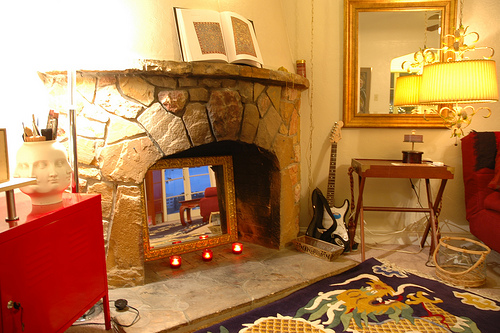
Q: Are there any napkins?
A: No, there are no napkins.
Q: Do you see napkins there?
A: No, there are no napkins.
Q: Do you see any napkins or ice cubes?
A: No, there are no napkins or ice cubes.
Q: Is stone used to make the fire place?
A: Yes, the fire place is made of stone.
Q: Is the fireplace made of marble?
A: No, the fireplace is made of stone.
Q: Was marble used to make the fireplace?
A: No, the fireplace is made of stone.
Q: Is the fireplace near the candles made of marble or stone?
A: The fire place is made of stone.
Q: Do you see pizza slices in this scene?
A: No, there are no pizza slices.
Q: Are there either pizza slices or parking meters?
A: No, there are no pizza slices or parking meters.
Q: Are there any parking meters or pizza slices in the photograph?
A: No, there are no pizza slices or parking meters.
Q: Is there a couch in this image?
A: Yes, there is a couch.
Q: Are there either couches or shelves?
A: Yes, there is a couch.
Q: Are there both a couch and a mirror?
A: Yes, there are both a couch and a mirror.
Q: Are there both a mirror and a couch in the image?
A: Yes, there are both a couch and a mirror.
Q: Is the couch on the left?
A: No, the couch is on the right of the image.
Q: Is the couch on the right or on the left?
A: The couch is on the right of the image.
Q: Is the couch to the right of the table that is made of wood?
A: Yes, the couch is to the right of the table.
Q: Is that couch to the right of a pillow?
A: No, the couch is to the right of the table.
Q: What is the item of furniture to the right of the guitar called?
A: The piece of furniture is a couch.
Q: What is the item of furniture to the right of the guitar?
A: The piece of furniture is a couch.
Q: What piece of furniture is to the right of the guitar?
A: The piece of furniture is a couch.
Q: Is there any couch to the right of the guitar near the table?
A: Yes, there is a couch to the right of the guitar.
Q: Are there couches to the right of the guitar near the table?
A: Yes, there is a couch to the right of the guitar.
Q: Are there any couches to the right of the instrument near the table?
A: Yes, there is a couch to the right of the guitar.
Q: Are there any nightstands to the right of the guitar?
A: No, there is a couch to the right of the guitar.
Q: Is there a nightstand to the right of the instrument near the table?
A: No, there is a couch to the right of the guitar.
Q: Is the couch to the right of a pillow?
A: No, the couch is to the right of the guitar.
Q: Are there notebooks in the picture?
A: No, there are no notebooks.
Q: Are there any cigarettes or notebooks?
A: No, there are no notebooks or cigarettes.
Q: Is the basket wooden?
A: Yes, the basket is wooden.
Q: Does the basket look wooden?
A: Yes, the basket is wooden.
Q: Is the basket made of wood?
A: Yes, the basket is made of wood.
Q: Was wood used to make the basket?
A: Yes, the basket is made of wood.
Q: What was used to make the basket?
A: The basket is made of wood.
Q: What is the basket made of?
A: The basket is made of wood.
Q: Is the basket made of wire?
A: No, the basket is made of wood.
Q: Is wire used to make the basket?
A: No, the basket is made of wood.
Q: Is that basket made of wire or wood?
A: The basket is made of wood.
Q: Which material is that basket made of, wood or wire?
A: The basket is made of wood.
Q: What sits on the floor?
A: The basket sits on the floor.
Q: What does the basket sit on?
A: The basket sits on the floor.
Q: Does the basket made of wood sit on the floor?
A: Yes, the basket sits on the floor.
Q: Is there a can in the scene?
A: No, there are no cans.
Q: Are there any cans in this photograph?
A: No, there are no cans.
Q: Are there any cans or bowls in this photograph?
A: No, there are no cans or bowls.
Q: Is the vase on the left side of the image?
A: Yes, the vase is on the left of the image.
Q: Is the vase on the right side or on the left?
A: The vase is on the left of the image.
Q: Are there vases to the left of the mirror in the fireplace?
A: Yes, there is a vase to the left of the mirror.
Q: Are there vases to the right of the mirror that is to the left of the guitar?
A: No, the vase is to the left of the mirror.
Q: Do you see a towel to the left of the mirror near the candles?
A: No, there is a vase to the left of the mirror.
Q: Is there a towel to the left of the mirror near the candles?
A: No, there is a vase to the left of the mirror.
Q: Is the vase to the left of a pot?
A: No, the vase is to the left of the mirror.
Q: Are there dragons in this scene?
A: Yes, there is a dragon.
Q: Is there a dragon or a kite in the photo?
A: Yes, there is a dragon.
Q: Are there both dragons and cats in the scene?
A: No, there is a dragon but no cats.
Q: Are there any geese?
A: No, there are no geese.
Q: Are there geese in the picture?
A: No, there are no geese.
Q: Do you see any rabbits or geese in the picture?
A: No, there are no geese or rabbits.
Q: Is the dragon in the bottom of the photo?
A: Yes, the dragon is in the bottom of the image.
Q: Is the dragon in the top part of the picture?
A: No, the dragon is in the bottom of the image.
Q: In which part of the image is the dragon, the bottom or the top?
A: The dragon is in the bottom of the image.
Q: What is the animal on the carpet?
A: The animal is a dragon.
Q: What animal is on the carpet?
A: The animal is a dragon.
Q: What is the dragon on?
A: The dragon is on the carpet.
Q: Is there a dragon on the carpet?
A: Yes, there is a dragon on the carpet.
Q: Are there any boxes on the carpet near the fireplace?
A: No, there is a dragon on the carpet.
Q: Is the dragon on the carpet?
A: Yes, the dragon is on the carpet.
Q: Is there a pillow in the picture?
A: No, there are no pillows.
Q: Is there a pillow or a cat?
A: No, there are no pillows or cats.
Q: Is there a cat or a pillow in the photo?
A: No, there are no pillows or cats.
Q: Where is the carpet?
A: The carpet is on the floor.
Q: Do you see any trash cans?
A: No, there are no trash cans.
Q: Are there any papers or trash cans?
A: No, there are no trash cans or papers.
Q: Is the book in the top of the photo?
A: Yes, the book is in the top of the image.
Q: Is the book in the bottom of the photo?
A: No, the book is in the top of the image.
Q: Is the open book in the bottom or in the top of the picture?
A: The book is in the top of the image.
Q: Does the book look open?
A: Yes, the book is open.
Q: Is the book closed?
A: No, the book is open.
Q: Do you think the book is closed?
A: No, the book is open.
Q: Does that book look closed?
A: No, the book is open.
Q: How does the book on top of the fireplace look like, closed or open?
A: The book is open.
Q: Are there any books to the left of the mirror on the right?
A: Yes, there is a book to the left of the mirror.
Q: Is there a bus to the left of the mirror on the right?
A: No, there is a book to the left of the mirror.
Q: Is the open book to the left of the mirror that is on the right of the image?
A: Yes, the book is to the left of the mirror.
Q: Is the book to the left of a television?
A: No, the book is to the left of the mirror.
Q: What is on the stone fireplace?
A: The book is on the fireplace.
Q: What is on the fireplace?
A: The book is on the fireplace.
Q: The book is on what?
A: The book is on the fireplace.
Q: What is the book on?
A: The book is on the fireplace.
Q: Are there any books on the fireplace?
A: Yes, there is a book on the fireplace.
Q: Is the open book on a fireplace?
A: Yes, the book is on a fireplace.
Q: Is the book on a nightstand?
A: No, the book is on a fireplace.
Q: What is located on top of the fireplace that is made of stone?
A: The book is on top of the fireplace.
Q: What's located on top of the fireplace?
A: The book is on top of the fireplace.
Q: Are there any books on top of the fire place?
A: Yes, there is a book on top of the fire place.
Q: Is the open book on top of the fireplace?
A: Yes, the book is on top of the fireplace.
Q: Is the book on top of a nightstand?
A: No, the book is on top of the fireplace.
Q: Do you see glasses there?
A: No, there are no glasses.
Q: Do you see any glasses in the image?
A: No, there are no glasses.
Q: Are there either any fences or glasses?
A: No, there are no glasses or fences.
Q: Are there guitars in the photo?
A: Yes, there is a guitar.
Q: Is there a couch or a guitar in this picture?
A: Yes, there is a guitar.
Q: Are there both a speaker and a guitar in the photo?
A: No, there is a guitar but no speakers.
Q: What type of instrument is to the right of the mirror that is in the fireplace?
A: The instrument is a guitar.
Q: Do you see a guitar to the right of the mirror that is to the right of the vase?
A: Yes, there is a guitar to the right of the mirror.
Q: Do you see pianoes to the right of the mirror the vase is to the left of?
A: No, there is a guitar to the right of the mirror.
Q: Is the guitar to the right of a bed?
A: No, the guitar is to the right of the mirror.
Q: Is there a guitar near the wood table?
A: Yes, there is a guitar near the table.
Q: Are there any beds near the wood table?
A: No, there is a guitar near the table.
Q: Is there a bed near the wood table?
A: No, there is a guitar near the table.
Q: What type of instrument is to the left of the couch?
A: The instrument is a guitar.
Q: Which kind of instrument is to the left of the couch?
A: The instrument is a guitar.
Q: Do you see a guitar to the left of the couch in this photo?
A: Yes, there is a guitar to the left of the couch.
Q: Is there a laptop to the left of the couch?
A: No, there is a guitar to the left of the couch.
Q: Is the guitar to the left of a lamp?
A: No, the guitar is to the left of a couch.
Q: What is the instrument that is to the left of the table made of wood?
A: The instrument is a guitar.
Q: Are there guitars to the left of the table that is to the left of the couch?
A: Yes, there is a guitar to the left of the table.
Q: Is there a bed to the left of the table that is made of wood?
A: No, there is a guitar to the left of the table.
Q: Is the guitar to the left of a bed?
A: No, the guitar is to the left of a table.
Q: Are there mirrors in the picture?
A: Yes, there is a mirror.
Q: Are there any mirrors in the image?
A: Yes, there is a mirror.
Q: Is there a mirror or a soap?
A: Yes, there is a mirror.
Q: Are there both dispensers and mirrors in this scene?
A: No, there is a mirror but no dispensers.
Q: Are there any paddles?
A: No, there are no paddles.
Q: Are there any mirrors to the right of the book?
A: Yes, there is a mirror to the right of the book.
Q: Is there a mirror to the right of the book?
A: Yes, there is a mirror to the right of the book.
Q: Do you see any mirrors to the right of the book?
A: Yes, there is a mirror to the right of the book.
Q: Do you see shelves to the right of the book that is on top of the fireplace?
A: No, there is a mirror to the right of the book.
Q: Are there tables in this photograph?
A: Yes, there is a table.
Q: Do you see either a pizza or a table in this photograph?
A: Yes, there is a table.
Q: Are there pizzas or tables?
A: Yes, there is a table.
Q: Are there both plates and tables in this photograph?
A: No, there is a table but no plates.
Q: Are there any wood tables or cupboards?
A: Yes, there is a wood table.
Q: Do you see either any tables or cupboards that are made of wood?
A: Yes, the table is made of wood.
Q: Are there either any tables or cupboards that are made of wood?
A: Yes, the table is made of wood.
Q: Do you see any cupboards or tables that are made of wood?
A: Yes, the table is made of wood.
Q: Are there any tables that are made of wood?
A: Yes, there is a table that is made of wood.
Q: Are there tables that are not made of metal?
A: Yes, there is a table that is made of wood.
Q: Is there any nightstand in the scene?
A: No, there are no nightstands.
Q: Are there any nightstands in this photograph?
A: No, there are no nightstands.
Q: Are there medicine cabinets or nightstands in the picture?
A: No, there are no nightstands or medicine cabinets.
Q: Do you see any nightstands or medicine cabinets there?
A: No, there are no nightstands or medicine cabinets.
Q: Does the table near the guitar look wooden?
A: Yes, the table is wooden.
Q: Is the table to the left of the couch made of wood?
A: Yes, the table is made of wood.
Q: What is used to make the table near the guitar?
A: The table is made of wood.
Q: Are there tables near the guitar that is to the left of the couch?
A: Yes, there is a table near the guitar.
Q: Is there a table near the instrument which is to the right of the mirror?
A: Yes, there is a table near the guitar.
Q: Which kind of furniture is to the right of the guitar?
A: The piece of furniture is a table.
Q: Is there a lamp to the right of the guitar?
A: No, there is a table to the right of the guitar.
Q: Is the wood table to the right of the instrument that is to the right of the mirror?
A: Yes, the table is to the right of the guitar.